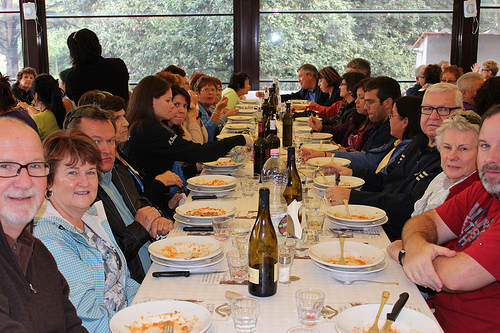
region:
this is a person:
[1, 113, 86, 329]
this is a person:
[31, 130, 139, 311]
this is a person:
[70, 109, 168, 250]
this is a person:
[423, 111, 499, 303]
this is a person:
[414, 120, 493, 201]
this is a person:
[391, 71, 481, 201]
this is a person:
[353, 77, 393, 164]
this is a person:
[335, 75, 365, 135]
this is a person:
[121, 73, 183, 200]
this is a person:
[166, 79, 226, 147]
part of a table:
[390, 274, 399, 286]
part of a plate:
[182, 309, 187, 318]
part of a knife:
[387, 314, 392, 320]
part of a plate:
[338, 240, 348, 262]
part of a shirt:
[93, 252, 98, 267]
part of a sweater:
[8, 267, 24, 289]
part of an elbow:
[438, 257, 472, 281]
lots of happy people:
[4, 28, 493, 331]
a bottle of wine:
[238, 175, 290, 302]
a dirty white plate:
[143, 229, 240, 279]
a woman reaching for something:
[123, 72, 258, 180]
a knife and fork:
[352, 283, 418, 330]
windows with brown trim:
[43, 7, 487, 73]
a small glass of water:
[227, 291, 267, 331]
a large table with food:
[120, 61, 430, 328]